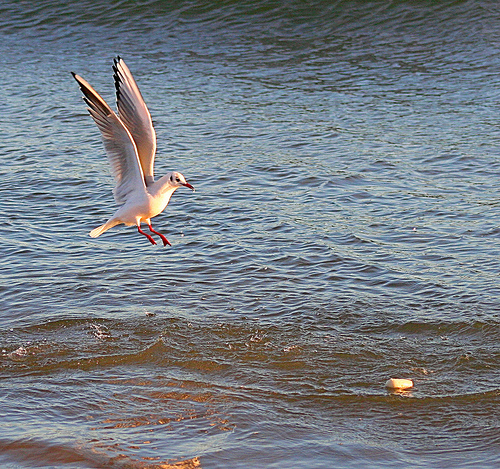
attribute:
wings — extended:
[71, 56, 158, 184]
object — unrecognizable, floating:
[385, 376, 413, 391]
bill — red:
[182, 182, 194, 191]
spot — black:
[168, 175, 171, 183]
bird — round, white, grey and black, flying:
[68, 53, 194, 245]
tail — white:
[88, 216, 118, 236]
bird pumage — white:
[112, 184, 168, 228]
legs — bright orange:
[135, 227, 169, 246]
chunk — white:
[383, 374, 413, 391]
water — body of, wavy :
[0, 1, 498, 464]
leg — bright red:
[132, 227, 155, 247]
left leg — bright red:
[147, 225, 171, 245]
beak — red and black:
[182, 180, 193, 190]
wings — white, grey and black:
[68, 50, 158, 206]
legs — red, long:
[136, 225, 171, 247]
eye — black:
[173, 177, 181, 181]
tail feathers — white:
[88, 220, 117, 236]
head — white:
[165, 170, 195, 189]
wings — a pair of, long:
[58, 37, 178, 201]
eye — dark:
[165, 174, 185, 187]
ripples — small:
[205, 291, 312, 354]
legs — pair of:
[135, 220, 184, 250]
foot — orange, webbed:
[139, 228, 176, 248]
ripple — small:
[348, 326, 498, 381]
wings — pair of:
[54, 55, 166, 198]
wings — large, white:
[20, 53, 166, 207]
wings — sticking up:
[66, 51, 170, 200]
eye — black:
[173, 172, 183, 182]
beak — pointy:
[178, 180, 196, 195]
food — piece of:
[381, 360, 411, 396]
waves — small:
[24, 314, 252, 378]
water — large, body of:
[23, 8, 469, 450]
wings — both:
[67, 27, 166, 199]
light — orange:
[75, 400, 235, 466]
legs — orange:
[135, 219, 173, 248]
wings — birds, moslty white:
[67, 42, 171, 180]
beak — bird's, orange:
[183, 184, 194, 194]